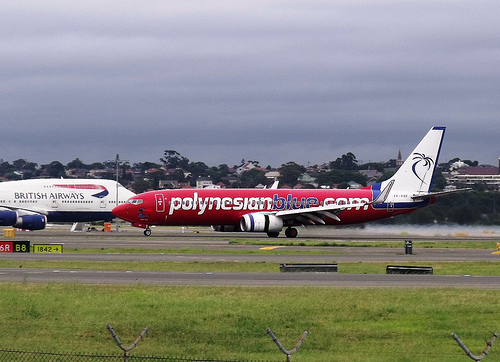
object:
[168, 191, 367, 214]
logo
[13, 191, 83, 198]
logo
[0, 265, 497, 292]
runway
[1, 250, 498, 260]
runway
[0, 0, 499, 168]
sky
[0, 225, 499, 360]
grass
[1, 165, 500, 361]
airfield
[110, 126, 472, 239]
airplane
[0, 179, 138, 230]
airplane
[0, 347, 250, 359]
barbed fence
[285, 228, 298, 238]
tire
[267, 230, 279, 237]
tire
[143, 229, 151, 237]
tire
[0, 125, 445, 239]
two airplanes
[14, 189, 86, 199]
lettering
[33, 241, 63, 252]
sign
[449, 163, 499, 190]
building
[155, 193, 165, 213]
door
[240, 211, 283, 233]
engine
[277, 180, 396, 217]
wing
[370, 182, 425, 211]
stripe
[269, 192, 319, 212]
word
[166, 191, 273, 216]
writing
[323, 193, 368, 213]
writing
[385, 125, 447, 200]
tail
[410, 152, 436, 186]
logo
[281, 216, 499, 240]
white smoke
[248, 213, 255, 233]
stripe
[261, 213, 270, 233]
stripe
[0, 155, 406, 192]
buildings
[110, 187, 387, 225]
body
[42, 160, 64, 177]
tree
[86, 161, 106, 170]
tree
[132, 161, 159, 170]
tree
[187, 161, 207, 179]
tree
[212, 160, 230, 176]
tree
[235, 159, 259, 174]
house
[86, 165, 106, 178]
house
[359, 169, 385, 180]
house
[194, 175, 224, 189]
house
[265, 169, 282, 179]
house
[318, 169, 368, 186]
distant tree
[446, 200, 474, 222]
distant tree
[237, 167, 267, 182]
distant tree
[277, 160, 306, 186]
distant tree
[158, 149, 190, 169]
distant tree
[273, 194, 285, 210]
lettering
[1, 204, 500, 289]
landing strip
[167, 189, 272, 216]
polynesian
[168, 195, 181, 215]
letter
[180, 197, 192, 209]
letter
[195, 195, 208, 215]
letter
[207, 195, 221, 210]
letter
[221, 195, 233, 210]
letter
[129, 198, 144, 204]
windows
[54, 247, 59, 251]
arrow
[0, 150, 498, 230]
background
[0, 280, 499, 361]
forefront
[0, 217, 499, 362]
ground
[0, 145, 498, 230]
distance